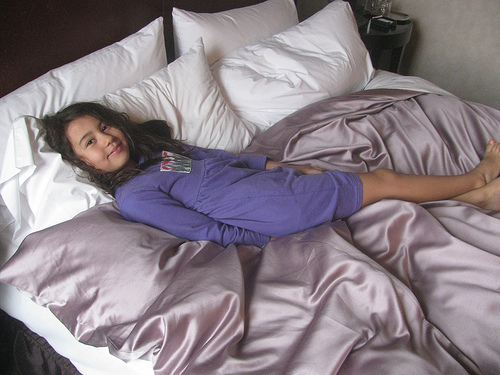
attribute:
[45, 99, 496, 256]
girl — laying, little, smiling, young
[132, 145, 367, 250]
nightgown — purple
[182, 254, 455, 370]
sheet — wrinkled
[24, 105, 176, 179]
hair — dark, curly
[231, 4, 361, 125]
pillow — here, white, propped, big, present, fluffy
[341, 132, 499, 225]
legs — crossed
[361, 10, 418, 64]
stand — black, here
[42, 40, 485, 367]
bed — fluffy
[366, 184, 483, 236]
leg — laying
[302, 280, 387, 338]
duvet — wrinkled, purple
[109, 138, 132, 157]
smile — small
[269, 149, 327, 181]
hand — here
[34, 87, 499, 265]
kid — here, lying, happy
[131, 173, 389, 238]
dress — purple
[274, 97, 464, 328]
bedding — nice